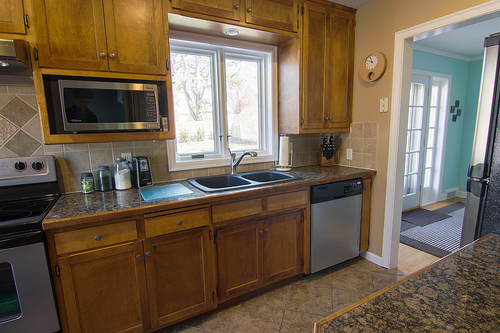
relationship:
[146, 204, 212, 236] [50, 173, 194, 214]
drawer below counter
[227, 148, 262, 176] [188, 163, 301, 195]
faucet above sink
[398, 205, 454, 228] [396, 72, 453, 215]
mat by door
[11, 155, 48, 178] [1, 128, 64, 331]
knobs on stove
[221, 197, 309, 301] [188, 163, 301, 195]
cabinets below sink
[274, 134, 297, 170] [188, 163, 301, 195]
towels by sink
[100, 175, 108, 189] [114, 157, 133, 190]
spices in jar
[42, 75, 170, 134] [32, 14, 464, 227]
microwave in kitchen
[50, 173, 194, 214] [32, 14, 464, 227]
counter in kitchen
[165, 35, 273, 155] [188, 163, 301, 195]
window by sink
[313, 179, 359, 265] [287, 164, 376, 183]
dishwasher under counter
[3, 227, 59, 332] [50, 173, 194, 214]
oven by counter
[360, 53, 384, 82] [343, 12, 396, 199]
clock on wall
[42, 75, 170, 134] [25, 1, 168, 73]
microwave under cabinets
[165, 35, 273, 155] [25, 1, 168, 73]
window by cabinets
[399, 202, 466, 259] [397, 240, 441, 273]
mat on floor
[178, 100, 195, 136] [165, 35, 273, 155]
sunlight through window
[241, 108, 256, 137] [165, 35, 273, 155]
daytime through window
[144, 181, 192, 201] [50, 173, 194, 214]
board on counter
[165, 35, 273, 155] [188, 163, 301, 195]
window above sink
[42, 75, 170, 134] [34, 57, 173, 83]
microwave in cabinet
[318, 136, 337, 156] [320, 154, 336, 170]
knives in block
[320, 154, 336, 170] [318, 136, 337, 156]
block has knives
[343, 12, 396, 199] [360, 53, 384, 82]
wall has clock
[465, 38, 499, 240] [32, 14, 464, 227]
refrigerator in kitchen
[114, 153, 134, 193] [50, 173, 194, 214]
jar on counter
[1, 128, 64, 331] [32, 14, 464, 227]
stove in kitchen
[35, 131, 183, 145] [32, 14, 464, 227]
shelf in kitchen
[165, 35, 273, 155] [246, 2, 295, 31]
window below cabinet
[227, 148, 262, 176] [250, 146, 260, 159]
faucet has tap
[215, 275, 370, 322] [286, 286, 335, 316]
floor has tile